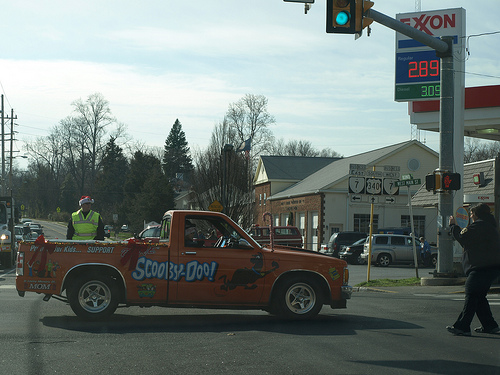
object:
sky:
[0, 0, 500, 171]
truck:
[13, 208, 350, 315]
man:
[66, 196, 105, 242]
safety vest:
[71, 208, 101, 241]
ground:
[0, 217, 500, 375]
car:
[324, 231, 369, 259]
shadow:
[38, 314, 426, 336]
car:
[361, 234, 438, 267]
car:
[16, 209, 353, 322]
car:
[244, 226, 305, 248]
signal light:
[326, 0, 377, 40]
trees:
[0, 93, 500, 232]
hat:
[79, 196, 95, 206]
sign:
[393, 7, 467, 103]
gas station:
[392, 6, 499, 289]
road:
[1, 218, 500, 375]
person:
[445, 204, 500, 338]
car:
[7, 225, 25, 254]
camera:
[449, 216, 454, 220]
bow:
[27, 234, 61, 278]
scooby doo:
[217, 252, 280, 291]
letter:
[131, 256, 218, 283]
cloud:
[0, 0, 500, 169]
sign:
[348, 162, 402, 205]